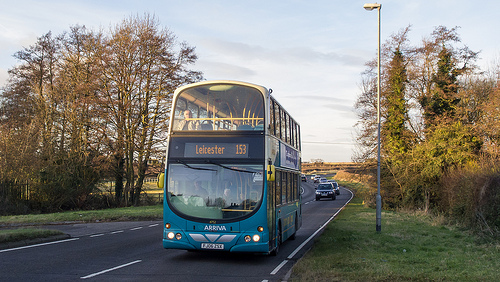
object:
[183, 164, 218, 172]
wiper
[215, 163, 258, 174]
wiper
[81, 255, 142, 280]
line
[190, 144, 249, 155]
bus sign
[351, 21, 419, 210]
trees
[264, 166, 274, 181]
mirror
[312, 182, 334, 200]
car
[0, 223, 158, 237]
road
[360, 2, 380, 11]
light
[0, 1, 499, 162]
sky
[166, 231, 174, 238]
headlight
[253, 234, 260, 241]
headlight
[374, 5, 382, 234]
post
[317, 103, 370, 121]
clouds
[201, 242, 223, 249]
licence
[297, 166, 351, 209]
traffic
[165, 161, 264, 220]
front windshield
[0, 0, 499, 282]
scene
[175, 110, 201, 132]
man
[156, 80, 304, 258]
bus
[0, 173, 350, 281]
road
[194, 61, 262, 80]
cloud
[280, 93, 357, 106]
cloud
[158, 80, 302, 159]
level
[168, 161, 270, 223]
window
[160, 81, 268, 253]
front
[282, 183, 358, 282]
side